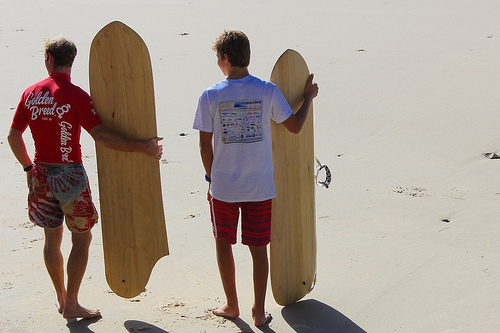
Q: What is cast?
A: Shadow.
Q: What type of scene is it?
A: Outdoor.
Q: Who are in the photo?
A: People.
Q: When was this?
A: Daytime.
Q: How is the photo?
A: Clear.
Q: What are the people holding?
A: Surfboards.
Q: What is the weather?
A: Sunny.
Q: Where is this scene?
A: Beach.